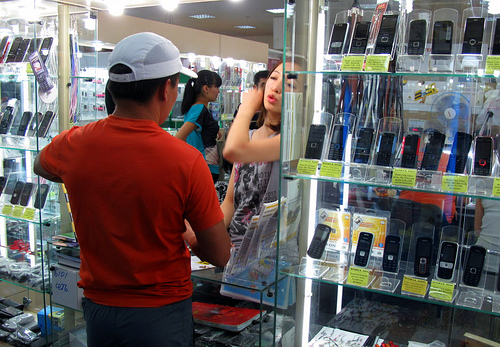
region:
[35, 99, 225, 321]
the shirt is orange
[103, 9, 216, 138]
the cap is white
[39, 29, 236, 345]
Man wearing a red shirt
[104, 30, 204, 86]
White hat on man's head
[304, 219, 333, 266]
Phone on the shelf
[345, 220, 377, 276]
Phone on the shelf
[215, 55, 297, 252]
Woman standing in front of man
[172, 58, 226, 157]
Woman wearing a blue shirt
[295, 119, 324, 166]
Cellphone on the shelf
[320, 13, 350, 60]
Cellphone on the shelf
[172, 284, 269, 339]
Book under the counter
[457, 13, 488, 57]
Cellphone on the shelf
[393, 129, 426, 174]
phone inside display case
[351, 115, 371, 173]
phone inside display case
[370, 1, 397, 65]
phone inside display case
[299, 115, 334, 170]
phone inside display case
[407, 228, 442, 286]
phone inside display case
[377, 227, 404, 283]
phone inside display case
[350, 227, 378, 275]
phone inside display case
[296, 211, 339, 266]
phone inside display case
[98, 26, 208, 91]
person wearing a cap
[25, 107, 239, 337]
person wearing an orange shirt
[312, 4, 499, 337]
these cellphones are on display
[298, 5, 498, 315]
these cell phones have physical keyboards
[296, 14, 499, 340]
these are not smart phones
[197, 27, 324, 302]
she is talking to the man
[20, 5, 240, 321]
he is wearing a red shirt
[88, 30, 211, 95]
he is wearing a white cap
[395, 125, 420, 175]
this phone is black and red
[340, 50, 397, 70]
the labels are a neon green color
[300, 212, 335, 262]
this phone is black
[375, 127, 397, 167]
this phone is black and blue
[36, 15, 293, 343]
woman is talking to man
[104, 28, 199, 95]
man wearing a hat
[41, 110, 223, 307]
man's shirt is red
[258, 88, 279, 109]
woman is wearing lip stick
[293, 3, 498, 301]
phones in a display case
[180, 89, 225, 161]
woman's shirt is blue and black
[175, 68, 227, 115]
woman's hair in pony tail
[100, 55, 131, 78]
hole in the hat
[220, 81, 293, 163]
woman's arm is over shoulder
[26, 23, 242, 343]
man standing behind counter